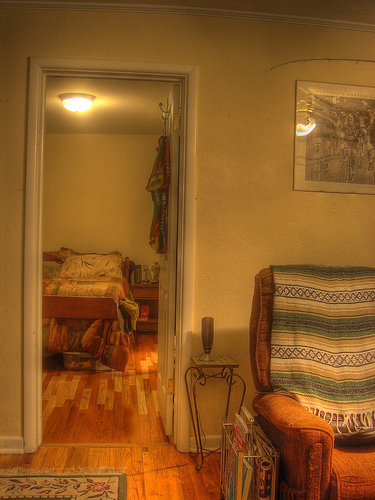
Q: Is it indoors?
A: Yes, it is indoors.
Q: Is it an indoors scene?
A: Yes, it is indoors.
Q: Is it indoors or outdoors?
A: It is indoors.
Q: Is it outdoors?
A: No, it is indoors.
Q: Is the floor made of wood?
A: Yes, the floor is made of wood.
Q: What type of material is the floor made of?
A: The floor is made of wood.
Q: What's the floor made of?
A: The floor is made of wood.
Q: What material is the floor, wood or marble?
A: The floor is made of wood.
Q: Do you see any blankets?
A: Yes, there is a blanket.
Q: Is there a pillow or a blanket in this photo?
A: Yes, there is a blanket.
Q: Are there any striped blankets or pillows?
A: Yes, there is a striped blanket.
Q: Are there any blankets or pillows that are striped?
A: Yes, the blanket is striped.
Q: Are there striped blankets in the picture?
A: Yes, there is a striped blanket.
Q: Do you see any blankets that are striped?
A: Yes, there is a blanket that is striped.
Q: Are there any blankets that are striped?
A: Yes, there is a blanket that is striped.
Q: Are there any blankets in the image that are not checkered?
A: Yes, there is a striped blanket.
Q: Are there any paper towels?
A: No, there are no paper towels.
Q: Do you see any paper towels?
A: No, there are no paper towels.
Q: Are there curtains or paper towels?
A: No, there are no paper towels or curtains.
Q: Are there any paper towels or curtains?
A: No, there are no paper towels or curtains.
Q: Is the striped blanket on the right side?
A: Yes, the blanket is on the right of the image.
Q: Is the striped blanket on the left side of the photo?
A: No, the blanket is on the right of the image.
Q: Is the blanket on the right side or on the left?
A: The blanket is on the right of the image.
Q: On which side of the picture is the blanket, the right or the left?
A: The blanket is on the right of the image.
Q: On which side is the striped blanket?
A: The blanket is on the right of the image.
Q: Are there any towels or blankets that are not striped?
A: No, there is a blanket but it is striped.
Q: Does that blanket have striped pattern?
A: Yes, the blanket is striped.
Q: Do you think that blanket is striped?
A: Yes, the blanket is striped.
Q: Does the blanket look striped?
A: Yes, the blanket is striped.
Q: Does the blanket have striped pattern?
A: Yes, the blanket is striped.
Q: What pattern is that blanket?
A: The blanket is striped.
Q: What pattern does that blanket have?
A: The blanket has striped pattern.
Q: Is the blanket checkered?
A: No, the blanket is striped.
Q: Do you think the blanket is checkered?
A: No, the blanket is striped.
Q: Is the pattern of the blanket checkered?
A: No, the blanket is striped.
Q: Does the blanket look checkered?
A: No, the blanket is striped.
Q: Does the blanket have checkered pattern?
A: No, the blanket is striped.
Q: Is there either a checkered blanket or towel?
A: No, there is a blanket but it is striped.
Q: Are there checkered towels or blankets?
A: No, there is a blanket but it is striped.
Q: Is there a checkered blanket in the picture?
A: No, there is a blanket but it is striped.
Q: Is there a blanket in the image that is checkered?
A: No, there is a blanket but it is striped.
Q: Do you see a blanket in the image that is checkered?
A: No, there is a blanket but it is striped.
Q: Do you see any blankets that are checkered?
A: No, there is a blanket but it is striped.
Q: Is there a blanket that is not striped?
A: No, there is a blanket but it is striped.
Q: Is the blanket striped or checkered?
A: The blanket is striped.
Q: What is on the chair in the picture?
A: The blanket is on the chair.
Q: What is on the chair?
A: The blanket is on the chair.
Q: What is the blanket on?
A: The blanket is on the chair.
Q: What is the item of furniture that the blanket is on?
A: The piece of furniture is a chair.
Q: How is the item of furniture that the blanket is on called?
A: The piece of furniture is a chair.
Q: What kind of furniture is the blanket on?
A: The blanket is on the chair.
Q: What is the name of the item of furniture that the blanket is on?
A: The piece of furniture is a chair.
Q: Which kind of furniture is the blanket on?
A: The blanket is on the chair.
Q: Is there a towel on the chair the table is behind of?
A: No, there is a blanket on the chair.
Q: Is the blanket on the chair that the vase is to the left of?
A: Yes, the blanket is on the chair.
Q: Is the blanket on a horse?
A: No, the blanket is on the chair.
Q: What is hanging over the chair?
A: The blanket is hanging over the chair.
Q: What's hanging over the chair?
A: The blanket is hanging over the chair.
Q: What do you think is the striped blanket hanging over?
A: The blanket is hanging over the chair.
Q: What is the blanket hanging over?
A: The blanket is hanging over the chair.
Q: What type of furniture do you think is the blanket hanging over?
A: The blanket is hanging over the chair.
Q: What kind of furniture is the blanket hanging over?
A: The blanket is hanging over the chair.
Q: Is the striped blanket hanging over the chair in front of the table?
A: Yes, the blanket is hanging over the chair.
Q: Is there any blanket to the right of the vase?
A: Yes, there is a blanket to the right of the vase.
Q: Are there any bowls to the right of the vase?
A: No, there is a blanket to the right of the vase.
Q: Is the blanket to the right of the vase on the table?
A: Yes, the blanket is to the right of the vase.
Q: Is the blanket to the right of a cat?
A: No, the blanket is to the right of the vase.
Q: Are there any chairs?
A: Yes, there is a chair.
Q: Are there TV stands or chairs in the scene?
A: Yes, there is a chair.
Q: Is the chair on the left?
A: No, the chair is on the right of the image.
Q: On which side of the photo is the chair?
A: The chair is on the right of the image.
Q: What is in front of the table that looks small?
A: The chair is in front of the table.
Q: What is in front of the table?
A: The chair is in front of the table.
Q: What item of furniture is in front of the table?
A: The piece of furniture is a chair.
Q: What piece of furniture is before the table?
A: The piece of furniture is a chair.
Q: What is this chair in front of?
A: The chair is in front of the table.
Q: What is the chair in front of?
A: The chair is in front of the table.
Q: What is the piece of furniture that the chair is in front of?
A: The piece of furniture is a table.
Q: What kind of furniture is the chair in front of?
A: The chair is in front of the table.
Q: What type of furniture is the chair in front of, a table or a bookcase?
A: The chair is in front of a table.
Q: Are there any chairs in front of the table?
A: Yes, there is a chair in front of the table.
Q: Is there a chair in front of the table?
A: Yes, there is a chair in front of the table.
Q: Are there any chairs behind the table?
A: No, the chair is in front of the table.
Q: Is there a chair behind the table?
A: No, the chair is in front of the table.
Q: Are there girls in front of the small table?
A: No, there is a chair in front of the table.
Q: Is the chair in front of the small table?
A: Yes, the chair is in front of the table.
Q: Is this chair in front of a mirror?
A: No, the chair is in front of the table.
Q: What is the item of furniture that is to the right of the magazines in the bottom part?
A: The piece of furniture is a chair.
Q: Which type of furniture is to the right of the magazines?
A: The piece of furniture is a chair.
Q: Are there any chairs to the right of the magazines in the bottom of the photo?
A: Yes, there is a chair to the right of the magazines.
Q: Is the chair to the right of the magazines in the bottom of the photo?
A: Yes, the chair is to the right of the magazines.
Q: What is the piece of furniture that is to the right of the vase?
A: The piece of furniture is a chair.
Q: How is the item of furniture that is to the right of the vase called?
A: The piece of furniture is a chair.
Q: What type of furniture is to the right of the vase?
A: The piece of furniture is a chair.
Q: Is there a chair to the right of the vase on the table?
A: Yes, there is a chair to the right of the vase.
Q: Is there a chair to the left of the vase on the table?
A: No, the chair is to the right of the vase.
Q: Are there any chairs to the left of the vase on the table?
A: No, the chair is to the right of the vase.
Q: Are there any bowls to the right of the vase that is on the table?
A: No, there is a chair to the right of the vase.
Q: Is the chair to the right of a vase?
A: Yes, the chair is to the right of a vase.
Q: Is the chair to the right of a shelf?
A: No, the chair is to the right of a vase.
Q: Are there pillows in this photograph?
A: Yes, there is a pillow.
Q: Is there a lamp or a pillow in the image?
A: Yes, there is a pillow.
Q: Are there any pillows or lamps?
A: Yes, there is a pillow.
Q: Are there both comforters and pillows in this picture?
A: Yes, there are both a pillow and a comforter.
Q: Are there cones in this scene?
A: No, there are no cones.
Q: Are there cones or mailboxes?
A: No, there are no cones or mailboxes.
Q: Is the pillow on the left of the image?
A: Yes, the pillow is on the left of the image.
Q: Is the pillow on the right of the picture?
A: No, the pillow is on the left of the image.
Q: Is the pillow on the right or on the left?
A: The pillow is on the left of the image.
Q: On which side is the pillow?
A: The pillow is on the left of the image.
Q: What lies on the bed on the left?
A: The pillow lies on the bed.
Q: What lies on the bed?
A: The pillow lies on the bed.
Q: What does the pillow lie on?
A: The pillow lies on the bed.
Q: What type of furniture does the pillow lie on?
A: The pillow lies on the bed.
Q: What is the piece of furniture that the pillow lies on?
A: The piece of furniture is a bed.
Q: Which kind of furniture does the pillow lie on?
A: The pillow lies on the bed.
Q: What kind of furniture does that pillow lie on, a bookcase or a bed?
A: The pillow lies on a bed.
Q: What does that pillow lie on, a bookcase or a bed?
A: The pillow lies on a bed.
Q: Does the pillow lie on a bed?
A: Yes, the pillow lies on a bed.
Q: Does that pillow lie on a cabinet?
A: No, the pillow lies on a bed.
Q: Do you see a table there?
A: Yes, there is a table.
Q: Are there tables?
A: Yes, there is a table.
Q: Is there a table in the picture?
A: Yes, there is a table.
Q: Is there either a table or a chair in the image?
A: Yes, there is a table.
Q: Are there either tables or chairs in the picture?
A: Yes, there is a table.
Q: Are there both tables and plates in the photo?
A: No, there is a table but no plates.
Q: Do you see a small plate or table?
A: Yes, there is a small table.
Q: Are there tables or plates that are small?
A: Yes, the table is small.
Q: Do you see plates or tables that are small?
A: Yes, the table is small.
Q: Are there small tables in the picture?
A: Yes, there is a small table.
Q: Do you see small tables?
A: Yes, there is a small table.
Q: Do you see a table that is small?
A: Yes, there is a table that is small.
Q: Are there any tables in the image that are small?
A: Yes, there is a table that is small.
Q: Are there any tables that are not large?
A: Yes, there is a small table.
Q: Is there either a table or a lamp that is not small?
A: No, there is a table but it is small.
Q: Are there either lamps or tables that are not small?
A: No, there is a table but it is small.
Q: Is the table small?
A: Yes, the table is small.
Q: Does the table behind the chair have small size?
A: Yes, the table is small.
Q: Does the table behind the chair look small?
A: Yes, the table is small.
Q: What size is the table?
A: The table is small.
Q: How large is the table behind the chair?
A: The table is small.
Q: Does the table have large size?
A: No, the table is small.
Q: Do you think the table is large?
A: No, the table is small.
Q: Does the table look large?
A: No, the table is small.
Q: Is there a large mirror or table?
A: No, there is a table but it is small.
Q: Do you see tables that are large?
A: No, there is a table but it is small.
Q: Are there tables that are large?
A: No, there is a table but it is small.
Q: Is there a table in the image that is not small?
A: No, there is a table but it is small.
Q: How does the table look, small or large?
A: The table is small.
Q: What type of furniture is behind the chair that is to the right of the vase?
A: The piece of furniture is a table.